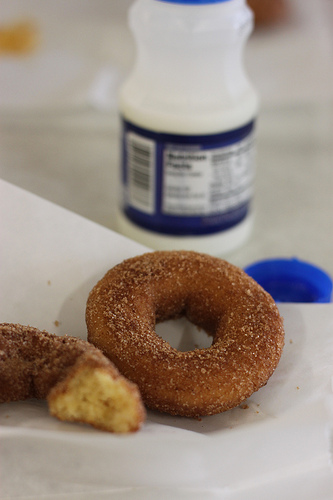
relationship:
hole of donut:
[149, 298, 221, 358] [80, 238, 293, 430]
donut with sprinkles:
[80, 238, 293, 430] [103, 251, 265, 367]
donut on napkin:
[0, 322, 147, 435] [0, 218, 324, 494]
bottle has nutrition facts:
[101, 0, 267, 263] [157, 140, 254, 220]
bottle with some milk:
[101, 0, 267, 263] [109, 189, 264, 264]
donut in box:
[0, 322, 147, 435] [4, 178, 332, 497]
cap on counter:
[147, 0, 240, 10] [4, 132, 331, 254]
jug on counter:
[101, 0, 267, 263] [4, 132, 331, 254]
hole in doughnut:
[149, 298, 221, 358] [80, 238, 293, 430]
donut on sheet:
[0, 322, 147, 435] [4, 178, 332, 497]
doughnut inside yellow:
[0, 308, 155, 441] [44, 360, 149, 436]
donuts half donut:
[0, 308, 155, 441] [0, 322, 147, 435]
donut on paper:
[0, 322, 147, 435] [4, 178, 332, 497]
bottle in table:
[101, 0, 267, 263] [0, 54, 331, 284]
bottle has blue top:
[101, 0, 267, 263] [153, 2, 231, 7]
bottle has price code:
[101, 0, 267, 263] [114, 125, 164, 222]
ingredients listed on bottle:
[157, 140, 254, 220] [101, 0, 267, 263]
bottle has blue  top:
[101, 0, 267, 263] [147, 0, 240, 10]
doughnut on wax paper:
[80, 238, 293, 430] [4, 178, 332, 497]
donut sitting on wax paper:
[0, 322, 147, 435] [4, 178, 332, 497]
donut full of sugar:
[0, 322, 147, 435] [0, 246, 292, 391]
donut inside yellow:
[0, 322, 147, 435] [44, 360, 149, 436]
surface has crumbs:
[4, 178, 332, 497] [31, 261, 70, 328]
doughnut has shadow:
[80, 238, 293, 430] [41, 271, 86, 331]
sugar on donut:
[0, 246, 292, 391] [0, 322, 147, 435]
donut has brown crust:
[0, 322, 147, 435] [0, 245, 289, 421]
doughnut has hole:
[80, 238, 293, 430] [149, 298, 221, 358]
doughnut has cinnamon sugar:
[80, 238, 293, 430] [103, 251, 265, 367]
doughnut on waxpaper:
[4, 178, 332, 497] [2, 178, 331, 496]